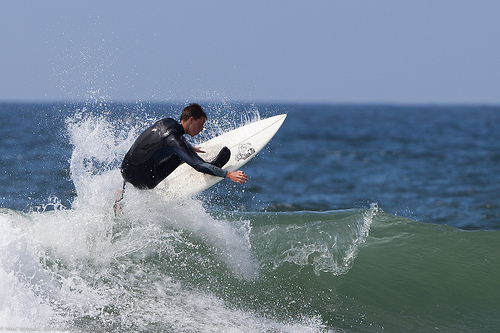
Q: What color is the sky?
A: Blue.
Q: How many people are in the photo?
A: One.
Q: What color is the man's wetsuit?
A: Black.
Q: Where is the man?
A: In the ocean.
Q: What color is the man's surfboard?
A: White.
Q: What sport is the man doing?
A: Surfing.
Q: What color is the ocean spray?
A: White.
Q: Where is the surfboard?
A: Under the man.